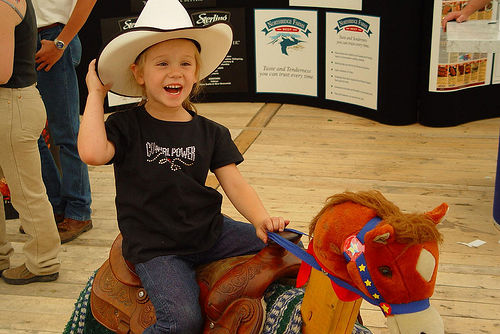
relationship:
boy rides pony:
[75, 1, 293, 333] [59, 189, 447, 333]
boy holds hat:
[75, 1, 293, 333] [94, 0, 235, 100]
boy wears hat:
[75, 1, 293, 333] [94, 0, 235, 100]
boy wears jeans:
[75, 1, 293, 333] [128, 214, 274, 334]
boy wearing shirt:
[75, 1, 293, 333] [101, 100, 247, 265]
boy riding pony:
[75, 1, 293, 333] [59, 189, 447, 333]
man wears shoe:
[21, 0, 100, 248] [56, 215, 95, 247]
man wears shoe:
[21, 0, 100, 248] [18, 218, 64, 237]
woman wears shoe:
[3, 1, 60, 287] [1, 261, 62, 285]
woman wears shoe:
[3, 1, 60, 287] [1, 253, 13, 274]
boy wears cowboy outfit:
[75, 1, 293, 333] [93, 0, 274, 332]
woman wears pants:
[3, 1, 60, 287] [0, 82, 69, 277]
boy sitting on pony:
[75, 1, 293, 333] [59, 189, 447, 333]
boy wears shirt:
[75, 1, 293, 333] [101, 100, 247, 265]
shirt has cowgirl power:
[101, 100, 247, 265] [143, 142, 197, 162]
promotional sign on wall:
[325, 8, 381, 112] [50, 1, 499, 133]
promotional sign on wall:
[252, 7, 321, 101] [50, 1, 499, 133]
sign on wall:
[423, 2, 499, 97] [50, 1, 499, 133]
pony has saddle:
[59, 189, 447, 333] [85, 223, 310, 332]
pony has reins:
[59, 189, 447, 333] [263, 213, 433, 315]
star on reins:
[357, 259, 368, 274] [263, 213, 433, 315]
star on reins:
[363, 277, 375, 288] [263, 213, 433, 315]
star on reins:
[370, 292, 383, 302] [263, 213, 433, 315]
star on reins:
[379, 301, 392, 315] [263, 213, 433, 315]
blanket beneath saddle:
[58, 263, 310, 333] [85, 223, 310, 332]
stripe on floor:
[200, 102, 284, 191] [5, 88, 499, 334]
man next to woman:
[21, 0, 100, 248] [3, 1, 60, 287]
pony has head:
[59, 189, 447, 333] [311, 187, 453, 333]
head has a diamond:
[311, 187, 453, 333] [412, 244, 438, 286]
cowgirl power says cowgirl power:
[143, 142, 197, 162] [143, 142, 198, 163]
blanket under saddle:
[58, 263, 310, 333] [85, 223, 310, 332]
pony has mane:
[59, 189, 447, 333] [306, 188, 448, 250]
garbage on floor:
[455, 237, 487, 249] [5, 88, 499, 334]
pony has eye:
[59, 189, 447, 333] [379, 266, 391, 276]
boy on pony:
[75, 1, 293, 333] [59, 189, 447, 333]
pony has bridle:
[59, 189, 447, 333] [341, 211, 433, 316]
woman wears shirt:
[3, 1, 60, 287] [1, 1, 40, 92]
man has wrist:
[21, 0, 100, 248] [54, 33, 72, 53]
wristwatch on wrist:
[53, 37, 68, 51] [54, 33, 72, 53]